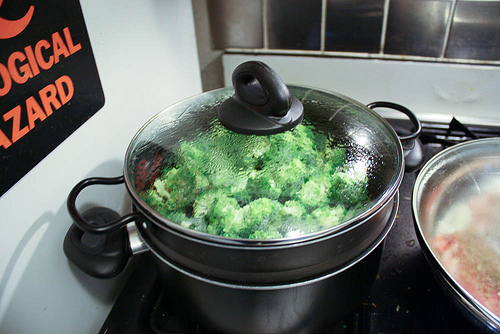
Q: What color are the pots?
A: Black.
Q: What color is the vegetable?
A: Green.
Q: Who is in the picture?
A: No one.